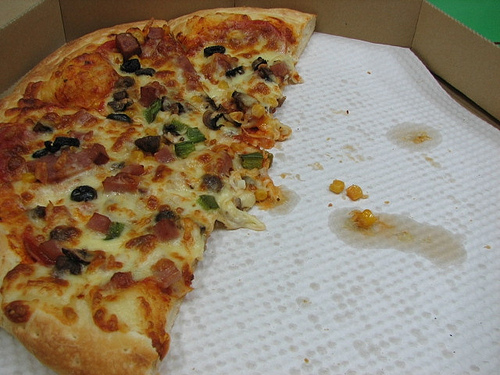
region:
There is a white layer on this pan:
[299, 251, 354, 330]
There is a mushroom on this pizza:
[53, 243, 94, 286]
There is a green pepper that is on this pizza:
[196, 187, 224, 239]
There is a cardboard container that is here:
[454, 30, 488, 96]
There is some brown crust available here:
[38, 293, 98, 368]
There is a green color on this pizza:
[473, 2, 498, 37]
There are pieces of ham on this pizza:
[108, 34, 160, 74]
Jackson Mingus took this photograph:
[116, 70, 406, 370]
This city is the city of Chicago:
[101, 70, 348, 346]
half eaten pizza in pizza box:
[15, 0, 492, 363]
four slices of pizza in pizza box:
[27, 0, 265, 362]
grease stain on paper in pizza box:
[324, 206, 456, 284]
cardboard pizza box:
[342, 3, 477, 98]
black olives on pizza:
[52, 174, 103, 206]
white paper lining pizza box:
[173, 31, 476, 368]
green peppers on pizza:
[173, 122, 208, 167]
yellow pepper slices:
[312, 171, 394, 233]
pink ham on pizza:
[84, 206, 116, 243]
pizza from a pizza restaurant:
[6, 9, 476, 366]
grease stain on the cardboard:
[329, 207, 461, 265]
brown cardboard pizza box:
[7, 1, 498, 133]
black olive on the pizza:
[68, 185, 95, 200]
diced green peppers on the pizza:
[176, 140, 194, 156]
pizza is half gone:
[8, 7, 315, 367]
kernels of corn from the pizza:
[328, 178, 362, 198]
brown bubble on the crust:
[5, 303, 28, 324]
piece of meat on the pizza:
[32, 148, 97, 181]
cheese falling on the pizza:
[219, 203, 264, 232]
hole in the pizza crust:
[72, 359, 83, 366]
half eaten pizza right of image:
[1, 6, 291, 367]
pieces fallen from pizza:
[325, 180, 384, 227]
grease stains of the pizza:
[382, 222, 474, 273]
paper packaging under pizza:
[294, 244, 494, 365]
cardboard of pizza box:
[395, 0, 498, 107]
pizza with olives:
[108, 75, 138, 96]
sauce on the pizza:
[94, 267, 135, 305]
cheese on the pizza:
[107, 236, 122, 253]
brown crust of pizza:
[25, 322, 155, 370]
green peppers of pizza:
[142, 100, 164, 124]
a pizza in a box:
[32, 9, 373, 374]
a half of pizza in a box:
[25, 26, 305, 354]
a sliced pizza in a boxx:
[43, 16, 329, 362]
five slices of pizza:
[44, 12, 304, 360]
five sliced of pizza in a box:
[28, 29, 408, 356]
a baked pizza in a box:
[22, 1, 264, 366]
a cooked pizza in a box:
[19, 29, 299, 373]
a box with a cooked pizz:
[46, 33, 308, 350]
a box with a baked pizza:
[16, 34, 332, 343]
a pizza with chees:
[46, 26, 274, 368]